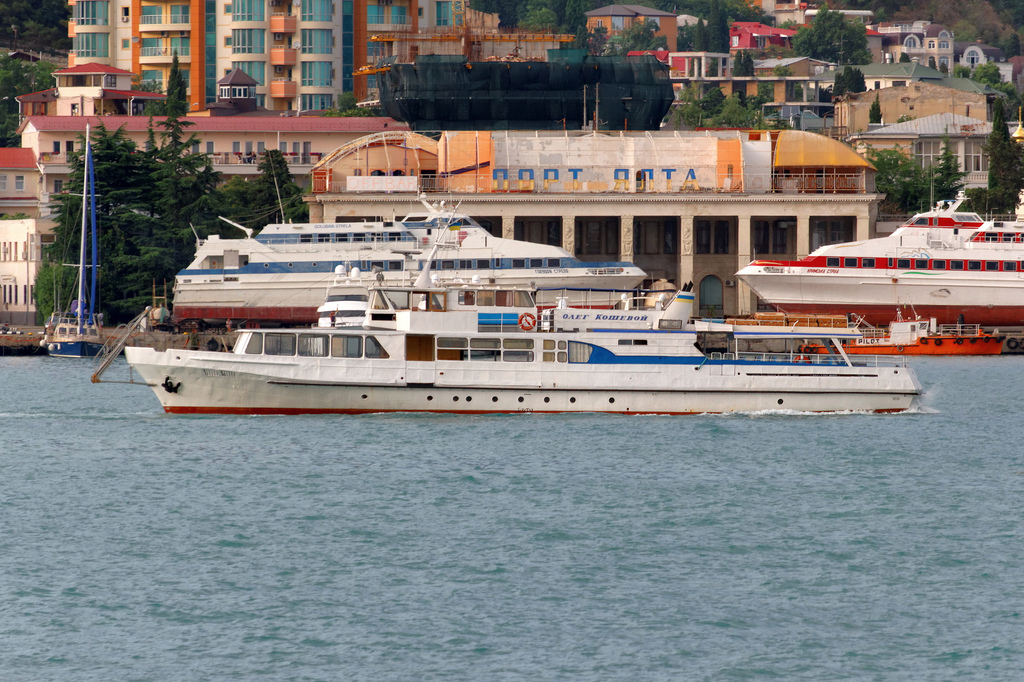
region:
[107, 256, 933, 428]
a boat on the water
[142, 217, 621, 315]
a boat on the water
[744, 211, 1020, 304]
a boat on the water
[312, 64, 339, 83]
a window on a building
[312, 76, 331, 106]
a window on a building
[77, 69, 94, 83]
a window on a building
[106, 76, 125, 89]
a window on a building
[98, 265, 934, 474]
long white boat in water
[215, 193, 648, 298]
large white yacht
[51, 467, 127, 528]
ripples in the blue water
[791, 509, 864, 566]
ripples in the blue water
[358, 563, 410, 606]
ripples in the blue water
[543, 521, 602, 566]
ripples in the blue water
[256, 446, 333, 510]
ripples in the blue water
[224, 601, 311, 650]
ripples in the blue water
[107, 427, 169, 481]
ripples in the blue water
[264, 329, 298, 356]
window on white boat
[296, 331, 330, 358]
window on white boat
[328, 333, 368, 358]
window on white boat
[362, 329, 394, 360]
window on white boat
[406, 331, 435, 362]
window on white boat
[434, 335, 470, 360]
window on white boat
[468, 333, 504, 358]
window on white boat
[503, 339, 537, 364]
window on white boat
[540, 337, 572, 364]
window on white boat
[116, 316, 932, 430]
Large boat in water.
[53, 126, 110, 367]
White and blue boat in water.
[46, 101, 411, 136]
Reddish brown roof on building.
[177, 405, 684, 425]
Bottom of boat is red.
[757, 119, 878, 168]
Yellow roof top on building.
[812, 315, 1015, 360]
Orange boat in water.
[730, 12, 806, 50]
Red building in distance.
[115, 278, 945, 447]
the boat is long in size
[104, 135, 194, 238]
the tree is green in color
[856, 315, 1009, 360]
the boat is small in size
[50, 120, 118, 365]
the boat is blue and white in color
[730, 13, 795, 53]
the house is red in color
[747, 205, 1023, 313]
the boat is big in size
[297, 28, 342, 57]
the window is closed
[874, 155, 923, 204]
the tree is light green in color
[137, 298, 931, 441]
A boat in the water.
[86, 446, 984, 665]
The wate is a little rough.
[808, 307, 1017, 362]
The boat is orange.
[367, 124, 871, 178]
The top of the building is orange.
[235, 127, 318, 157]
Windows ont he building.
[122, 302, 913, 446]
The boat is white.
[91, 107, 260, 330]
A tree in front of the building.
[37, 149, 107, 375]
A blue sailboat in the water.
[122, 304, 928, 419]
a long white boat floats in the water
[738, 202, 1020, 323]
a large red and white boat near the tug boat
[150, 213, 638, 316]
a large blue and white boat next to the sailboat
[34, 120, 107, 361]
the sailboat has no sail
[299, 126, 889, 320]
a beige building right by the water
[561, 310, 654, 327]
blue letters on the front of the boat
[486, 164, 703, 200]
the letters on the building are blue and yellow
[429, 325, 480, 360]
window on a boat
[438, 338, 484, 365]
window on a boat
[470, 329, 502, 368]
window on a boat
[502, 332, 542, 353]
window on a boat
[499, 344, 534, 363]
window on a boat